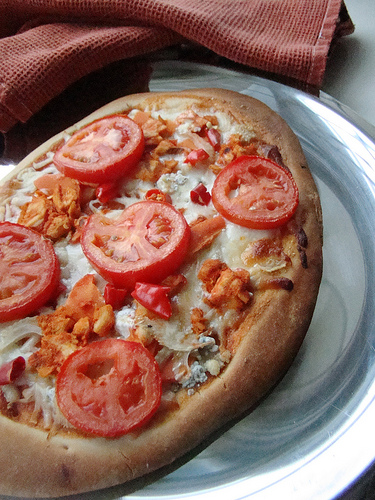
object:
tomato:
[52, 115, 144, 185]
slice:
[211, 154, 299, 231]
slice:
[53, 112, 144, 183]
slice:
[78, 200, 191, 289]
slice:
[55, 338, 162, 438]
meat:
[28, 274, 114, 380]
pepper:
[131, 282, 173, 320]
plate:
[0, 59, 375, 500]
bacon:
[28, 273, 116, 377]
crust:
[0, 87, 323, 500]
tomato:
[212, 154, 299, 230]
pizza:
[1, 87, 325, 500]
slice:
[0, 221, 60, 323]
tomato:
[0, 221, 61, 324]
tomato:
[56, 339, 162, 438]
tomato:
[81, 200, 192, 288]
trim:
[303, 1, 357, 88]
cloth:
[0, 0, 356, 134]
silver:
[0, 59, 375, 500]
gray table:
[325, 0, 375, 127]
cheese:
[2, 99, 279, 433]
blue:
[183, 362, 209, 388]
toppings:
[0, 109, 309, 438]